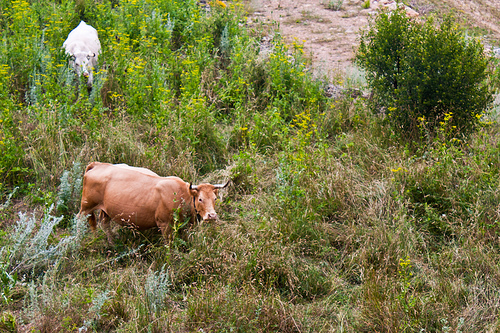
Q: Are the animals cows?
A: Yes, all the animals are cows.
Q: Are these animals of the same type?
A: Yes, all the animals are cows.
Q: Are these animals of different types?
A: No, all the animals are cows.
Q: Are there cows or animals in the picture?
A: Yes, there is a cow.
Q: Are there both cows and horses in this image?
A: No, there is a cow but no horses.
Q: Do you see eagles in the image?
A: No, there are no eagles.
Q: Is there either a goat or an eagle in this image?
A: No, there are no eagles or goats.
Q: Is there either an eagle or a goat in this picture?
A: No, there are no eagles or goats.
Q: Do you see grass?
A: Yes, there is grass.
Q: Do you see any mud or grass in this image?
A: Yes, there is grass.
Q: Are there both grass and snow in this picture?
A: No, there is grass but no snow.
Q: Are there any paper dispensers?
A: No, there are no paper dispensers.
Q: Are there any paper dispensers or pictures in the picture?
A: No, there are no paper dispensers or pictures.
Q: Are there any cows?
A: Yes, there is a cow.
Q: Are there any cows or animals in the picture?
A: Yes, there is a cow.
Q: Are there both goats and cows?
A: No, there is a cow but no goats.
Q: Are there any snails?
A: No, there are no snails.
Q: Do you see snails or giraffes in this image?
A: No, there are no snails or giraffes.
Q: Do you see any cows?
A: Yes, there is a cow.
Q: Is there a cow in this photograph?
A: Yes, there is a cow.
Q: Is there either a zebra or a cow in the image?
A: Yes, there is a cow.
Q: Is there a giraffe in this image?
A: No, there are no giraffes.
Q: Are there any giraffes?
A: No, there are no giraffes.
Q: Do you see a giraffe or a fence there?
A: No, there are no giraffes or fences.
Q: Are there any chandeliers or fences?
A: No, there are no fences or chandeliers.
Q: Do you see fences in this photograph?
A: No, there are no fences.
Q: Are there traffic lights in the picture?
A: No, there are no traffic lights.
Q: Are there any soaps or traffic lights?
A: No, there are no traffic lights or soaps.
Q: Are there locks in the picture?
A: No, there are no locks.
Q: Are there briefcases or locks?
A: No, there are no locks or briefcases.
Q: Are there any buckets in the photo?
A: No, there are no buckets.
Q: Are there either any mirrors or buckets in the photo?
A: No, there are no buckets or mirrors.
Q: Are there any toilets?
A: No, there are no toilets.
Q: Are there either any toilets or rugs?
A: No, there are no toilets or rugs.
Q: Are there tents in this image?
A: No, there are no tents.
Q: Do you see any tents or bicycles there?
A: No, there are no tents or bicycles.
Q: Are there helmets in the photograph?
A: No, there are no helmets.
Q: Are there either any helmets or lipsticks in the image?
A: No, there are no helmets or lipsticks.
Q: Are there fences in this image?
A: No, there are no fences.